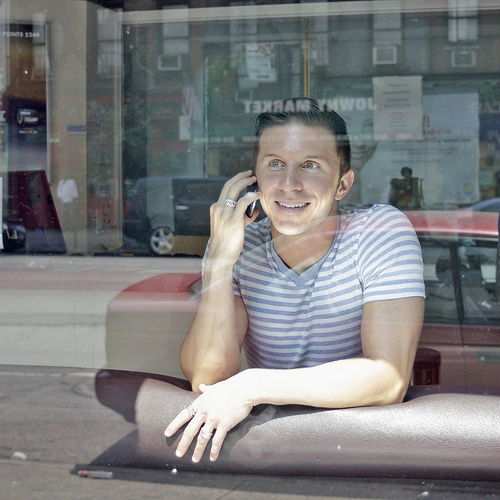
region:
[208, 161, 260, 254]
black cell phone in hand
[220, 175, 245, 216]
a ring in a finger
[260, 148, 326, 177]
the eyes are blue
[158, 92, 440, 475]
man wears a striped shirt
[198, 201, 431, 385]
a blue and white shirt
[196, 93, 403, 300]
man has short hair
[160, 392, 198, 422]
a ring in the index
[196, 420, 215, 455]
a ring in finger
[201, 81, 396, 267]
This man is talking on the phone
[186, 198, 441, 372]
The shirt is striped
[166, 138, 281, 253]
He is holding a phone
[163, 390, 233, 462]
Rings are on his fingers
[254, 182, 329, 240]
He is smiling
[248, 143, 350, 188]
Eyes are blue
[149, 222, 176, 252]
car tire in reflection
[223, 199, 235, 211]
ring on the man's finger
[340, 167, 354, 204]
left ear on man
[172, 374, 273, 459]
the man's left hand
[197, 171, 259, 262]
the man's right hand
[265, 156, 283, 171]
the man's right eye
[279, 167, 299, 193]
the nose on the man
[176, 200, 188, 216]
handle on the door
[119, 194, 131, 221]
brake light in reflection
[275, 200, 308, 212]
the man's teeth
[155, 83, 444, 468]
man on the phone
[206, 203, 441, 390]
blue and white stripes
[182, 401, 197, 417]
ring around the finger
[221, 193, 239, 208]
ring around the ring finger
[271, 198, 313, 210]
mouth is slightly open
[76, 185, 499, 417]
reflection of a red car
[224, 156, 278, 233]
fingers around the phone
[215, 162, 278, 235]
phone lifted up to the ear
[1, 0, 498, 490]
man behind a window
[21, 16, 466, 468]
a man looking through the glass window of a shop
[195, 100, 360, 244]
a man talking on a cellphone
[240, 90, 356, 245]
the head of a man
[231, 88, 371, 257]
a man who is smiling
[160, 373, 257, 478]
the hand of a man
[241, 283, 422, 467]
the arm of a man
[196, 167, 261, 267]
the hand of a man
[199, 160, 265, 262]
a man holding a cellphone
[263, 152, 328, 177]
the eyes of a man